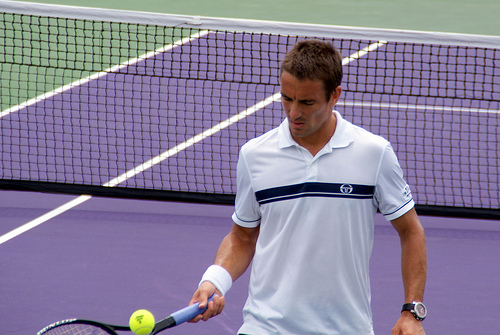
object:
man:
[188, 38, 430, 334]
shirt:
[232, 112, 415, 334]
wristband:
[199, 263, 234, 296]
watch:
[402, 299, 429, 320]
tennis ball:
[126, 309, 157, 333]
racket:
[32, 292, 218, 334]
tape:
[176, 305, 200, 320]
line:
[0, 93, 277, 242]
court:
[3, 0, 500, 335]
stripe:
[255, 179, 374, 204]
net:
[1, 2, 494, 211]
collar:
[333, 111, 354, 149]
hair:
[281, 39, 342, 103]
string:
[112, 26, 134, 190]